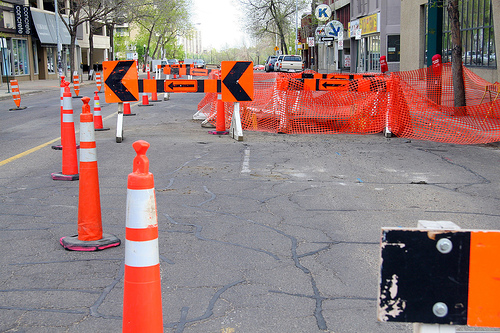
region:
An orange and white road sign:
[126, 128, 175, 332]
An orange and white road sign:
[82, 96, 104, 248]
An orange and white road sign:
[59, 84, 76, 178]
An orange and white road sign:
[94, 85, 109, 132]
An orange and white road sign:
[6, 72, 26, 121]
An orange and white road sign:
[71, 68, 80, 93]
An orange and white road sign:
[92, 66, 109, 101]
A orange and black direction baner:
[98, 55, 252, 115]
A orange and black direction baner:
[277, 70, 391, 91]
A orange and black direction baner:
[379, 216, 499, 331]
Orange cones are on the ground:
[22, 49, 315, 325]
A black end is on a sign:
[360, 200, 479, 331]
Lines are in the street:
[194, 201, 419, 331]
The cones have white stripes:
[109, 181, 271, 326]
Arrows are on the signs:
[87, 46, 408, 123]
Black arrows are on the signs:
[83, 55, 363, 150]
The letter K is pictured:
[296, 6, 371, 44]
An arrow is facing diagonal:
[313, 20, 376, 35]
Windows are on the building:
[410, 3, 490, 65]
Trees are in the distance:
[112, 11, 229, 72]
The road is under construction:
[35, 33, 498, 288]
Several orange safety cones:
[37, 55, 177, 315]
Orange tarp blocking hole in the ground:
[203, 45, 486, 161]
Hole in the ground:
[220, 88, 447, 158]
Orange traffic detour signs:
[100, 31, 391, 148]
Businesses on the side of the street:
[282, 4, 494, 138]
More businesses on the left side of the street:
[7, 6, 207, 97]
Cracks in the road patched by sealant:
[7, 142, 473, 324]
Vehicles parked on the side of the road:
[256, 40, 312, 82]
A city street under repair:
[3, 41, 489, 317]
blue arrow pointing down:
[325, 21, 344, 39]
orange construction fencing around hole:
[202, 73, 499, 143]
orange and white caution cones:
[60, 77, 172, 331]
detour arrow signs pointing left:
[102, 57, 255, 101]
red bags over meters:
[376, 52, 447, 74]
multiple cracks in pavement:
[185, 172, 335, 319]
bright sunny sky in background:
[201, 3, 236, 44]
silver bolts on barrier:
[430, 235, 455, 320]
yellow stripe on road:
[0, 133, 58, 173]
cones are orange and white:
[33, 67, 209, 331]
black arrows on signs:
[77, 53, 257, 114]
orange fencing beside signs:
[229, 72, 498, 152]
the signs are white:
[311, 3, 355, 51]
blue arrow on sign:
[316, 16, 349, 39]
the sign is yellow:
[342, 4, 385, 51]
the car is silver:
[270, 45, 304, 82]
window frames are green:
[419, 1, 498, 68]